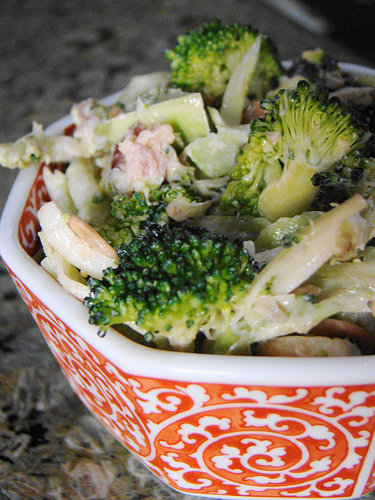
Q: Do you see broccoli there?
A: Yes, there is broccoli.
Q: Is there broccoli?
A: Yes, there is broccoli.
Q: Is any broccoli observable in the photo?
A: Yes, there is broccoli.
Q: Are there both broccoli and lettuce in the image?
A: No, there is broccoli but no lettuce.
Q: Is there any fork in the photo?
A: No, there are no forks.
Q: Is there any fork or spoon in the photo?
A: No, there are no forks or spoons.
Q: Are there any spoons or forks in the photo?
A: No, there are no forks or spoons.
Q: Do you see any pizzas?
A: No, there are no pizzas.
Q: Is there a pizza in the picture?
A: No, there are no pizzas.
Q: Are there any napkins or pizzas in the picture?
A: No, there are no pizzas or napkins.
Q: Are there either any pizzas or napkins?
A: No, there are no pizzas or napkins.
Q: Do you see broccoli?
A: Yes, there is broccoli.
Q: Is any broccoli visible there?
A: Yes, there is broccoli.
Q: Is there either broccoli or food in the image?
A: Yes, there is broccoli.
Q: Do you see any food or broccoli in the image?
A: Yes, there is broccoli.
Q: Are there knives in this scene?
A: No, there are no knives.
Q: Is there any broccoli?
A: Yes, there is broccoli.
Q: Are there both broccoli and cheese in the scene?
A: No, there is broccoli but no cheese.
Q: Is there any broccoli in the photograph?
A: Yes, there is broccoli.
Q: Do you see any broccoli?
A: Yes, there is broccoli.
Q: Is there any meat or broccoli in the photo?
A: Yes, there is broccoli.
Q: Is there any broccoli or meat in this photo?
A: Yes, there is broccoli.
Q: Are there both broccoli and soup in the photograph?
A: No, there is broccoli but no soup.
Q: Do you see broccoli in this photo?
A: Yes, there is broccoli.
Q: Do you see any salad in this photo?
A: Yes, there is salad.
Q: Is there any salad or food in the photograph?
A: Yes, there is salad.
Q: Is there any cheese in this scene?
A: No, there is no cheese.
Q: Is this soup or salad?
A: This is salad.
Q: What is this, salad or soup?
A: This is salad.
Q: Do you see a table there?
A: Yes, there is a table.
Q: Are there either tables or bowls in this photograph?
A: Yes, there is a table.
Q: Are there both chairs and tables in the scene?
A: No, there is a table but no chairs.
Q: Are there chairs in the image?
A: No, there are no chairs.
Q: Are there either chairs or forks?
A: No, there are no chairs or forks.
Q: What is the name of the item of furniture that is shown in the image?
A: The piece of furniture is a table.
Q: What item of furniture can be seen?
A: The piece of furniture is a table.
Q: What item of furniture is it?
A: The piece of furniture is a table.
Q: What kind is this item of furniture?
A: That is a table.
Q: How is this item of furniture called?
A: That is a table.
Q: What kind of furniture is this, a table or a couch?
A: That is a table.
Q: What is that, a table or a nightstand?
A: That is a table.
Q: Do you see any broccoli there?
A: Yes, there is broccoli.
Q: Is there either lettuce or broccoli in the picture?
A: Yes, there is broccoli.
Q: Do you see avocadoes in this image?
A: No, there are no avocadoes.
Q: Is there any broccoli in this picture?
A: Yes, there is broccoli.